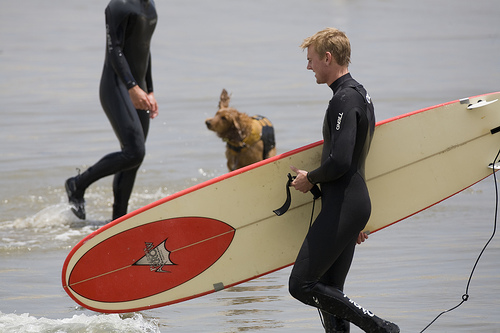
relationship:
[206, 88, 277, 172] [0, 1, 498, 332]
dog in water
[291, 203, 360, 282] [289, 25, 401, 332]
thigh of surfer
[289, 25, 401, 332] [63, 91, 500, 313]
surfer has surfboard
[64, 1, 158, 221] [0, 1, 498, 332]
surfer in water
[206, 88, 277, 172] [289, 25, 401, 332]
dog behind surfer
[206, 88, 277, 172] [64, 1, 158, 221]
dog by surfer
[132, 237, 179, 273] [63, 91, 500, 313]
logo on surfboard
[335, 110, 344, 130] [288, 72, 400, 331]
logo on wetsuit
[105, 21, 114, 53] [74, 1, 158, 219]
logo on wetsuit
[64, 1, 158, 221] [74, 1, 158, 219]
surfer in wetsuit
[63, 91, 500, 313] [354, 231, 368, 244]
surfboard in hand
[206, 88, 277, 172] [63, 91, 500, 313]
dog behind surfboard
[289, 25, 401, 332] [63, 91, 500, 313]
surfer holding surfboard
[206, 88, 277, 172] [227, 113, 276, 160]
dog wearing harness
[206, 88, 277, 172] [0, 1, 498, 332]
dog standing in water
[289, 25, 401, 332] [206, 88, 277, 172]
surfer standing by dog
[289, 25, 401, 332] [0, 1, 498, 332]
surfer in water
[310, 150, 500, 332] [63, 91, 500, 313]
cord attached to surfboard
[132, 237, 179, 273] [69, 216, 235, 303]
logo on spot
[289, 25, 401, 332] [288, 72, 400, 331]
surfer wearing wetsuit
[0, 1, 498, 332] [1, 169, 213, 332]
water has splashes